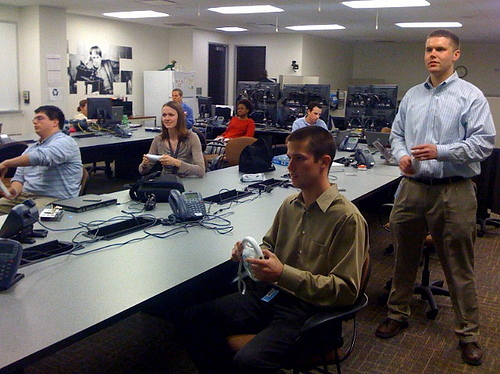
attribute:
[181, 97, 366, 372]
person — pictured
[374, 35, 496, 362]
person — pictured, standing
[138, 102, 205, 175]
person — pictured, sitting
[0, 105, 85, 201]
person — pictured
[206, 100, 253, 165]
person — pictured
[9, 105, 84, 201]
person — sitting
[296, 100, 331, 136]
person — sitting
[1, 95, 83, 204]
person — sitting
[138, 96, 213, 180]
person — sitting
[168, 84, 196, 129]
person — sitting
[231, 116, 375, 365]
person — sitting